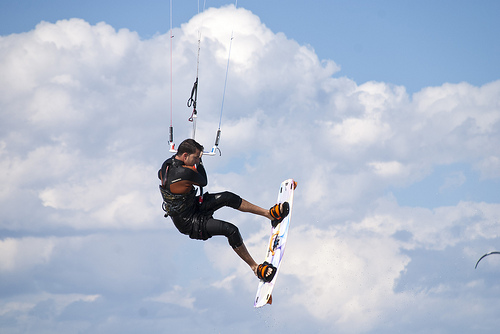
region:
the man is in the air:
[153, 150, 313, 291]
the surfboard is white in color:
[246, 161, 323, 311]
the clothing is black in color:
[147, 156, 237, 241]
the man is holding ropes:
[140, 80, 320, 285]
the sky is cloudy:
[235, 76, 490, 220]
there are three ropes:
[146, 48, 267, 149]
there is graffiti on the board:
[264, 221, 289, 257]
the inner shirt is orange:
[168, 180, 190, 190]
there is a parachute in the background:
[455, 236, 498, 267]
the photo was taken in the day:
[0, 66, 498, 313]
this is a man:
[155, 130, 309, 289]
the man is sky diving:
[125, 146, 305, 296]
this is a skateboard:
[258, 176, 305, 307]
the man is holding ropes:
[166, 71, 230, 161]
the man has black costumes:
[169, 181, 201, 216]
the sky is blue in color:
[361, 0, 497, 60]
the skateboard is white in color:
[248, 178, 300, 315]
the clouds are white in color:
[356, 97, 466, 155]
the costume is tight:
[196, 223, 226, 235]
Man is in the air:
[159, 142, 304, 315]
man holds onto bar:
[165, 3, 220, 157]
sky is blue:
[2, 1, 498, 332]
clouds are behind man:
[1, 12, 492, 330]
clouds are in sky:
[4, 10, 496, 330]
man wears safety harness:
[150, 141, 210, 210]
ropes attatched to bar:
[167, 0, 224, 157]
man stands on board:
[255, 175, 294, 310]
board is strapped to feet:
[246, 175, 293, 310]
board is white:
[255, 177, 285, 309]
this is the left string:
[165, 25, 179, 142]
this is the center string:
[191, 30, 201, 147]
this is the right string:
[210, 29, 242, 154]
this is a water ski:
[257, 155, 298, 311]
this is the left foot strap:
[246, 192, 298, 229]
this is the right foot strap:
[251, 248, 283, 287]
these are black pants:
[183, 182, 260, 249]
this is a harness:
[153, 150, 221, 245]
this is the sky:
[396, 31, 458, 85]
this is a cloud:
[241, 67, 317, 135]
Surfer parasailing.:
[113, 99, 331, 319]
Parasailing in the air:
[122, 105, 322, 319]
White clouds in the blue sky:
[86, 58, 331, 293]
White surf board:
[251, 174, 363, 331]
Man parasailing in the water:
[148, 140, 243, 240]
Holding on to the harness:
[137, 85, 307, 275]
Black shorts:
[176, 180, 286, 270]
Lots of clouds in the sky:
[80, 55, 187, 117]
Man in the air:
[170, 115, 328, 320]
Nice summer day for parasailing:
[78, 82, 375, 326]